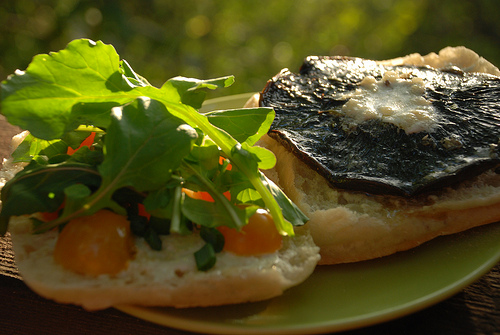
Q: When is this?
A: Daytime.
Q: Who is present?
A: Nobody.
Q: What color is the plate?
A: Green.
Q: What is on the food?
A: Vegetables.